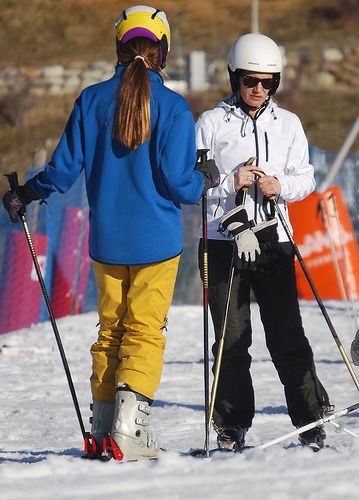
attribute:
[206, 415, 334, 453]
ski boots — pair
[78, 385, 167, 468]
ski boots — pair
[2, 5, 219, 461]
skier — female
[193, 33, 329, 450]
skier — female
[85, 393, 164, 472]
boots — metallic , gray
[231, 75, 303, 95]
glasses — black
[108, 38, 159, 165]
pony tail — woman's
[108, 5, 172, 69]
helmet — purple, gold, white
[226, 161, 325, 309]
pole — long, black, yellow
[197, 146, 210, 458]
ski pole — black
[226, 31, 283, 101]
helmet — white, skier's , ski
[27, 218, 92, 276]
barrier — protective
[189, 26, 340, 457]
woman — concerned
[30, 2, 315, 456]
skiers — oppositely-faced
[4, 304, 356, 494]
snow — white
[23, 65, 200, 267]
sweater — dark blue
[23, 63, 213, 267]
jacket — blue , fleece, ski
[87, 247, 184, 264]
trim — black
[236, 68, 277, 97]
sunglasses — black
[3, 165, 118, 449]
pole — ski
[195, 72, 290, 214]
sweater — black, white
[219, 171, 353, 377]
poles — black, yellow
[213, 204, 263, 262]
glove — grey, black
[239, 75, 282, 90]
sunglasses — dark